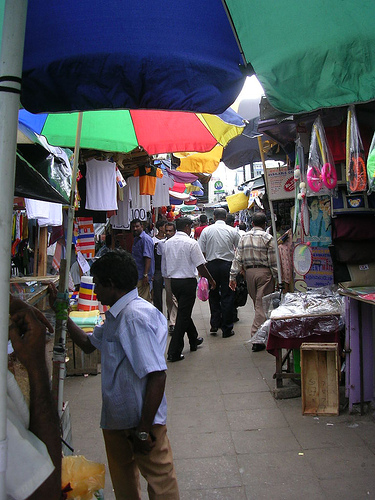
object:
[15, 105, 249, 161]
umbrella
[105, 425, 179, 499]
pants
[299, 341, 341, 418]
box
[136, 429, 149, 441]
watch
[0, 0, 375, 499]
market place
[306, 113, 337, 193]
item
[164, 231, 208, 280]
shirt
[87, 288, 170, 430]
shirt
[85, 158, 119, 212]
shirt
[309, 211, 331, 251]
shirt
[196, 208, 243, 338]
person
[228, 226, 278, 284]
shirt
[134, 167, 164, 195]
shirt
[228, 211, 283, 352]
man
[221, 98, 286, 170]
canopy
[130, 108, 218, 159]
panel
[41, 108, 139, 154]
panel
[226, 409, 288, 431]
stone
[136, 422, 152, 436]
wrist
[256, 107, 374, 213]
display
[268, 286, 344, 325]
table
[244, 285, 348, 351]
plastic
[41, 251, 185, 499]
man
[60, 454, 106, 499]
bag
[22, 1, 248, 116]
fabric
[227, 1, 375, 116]
fabric